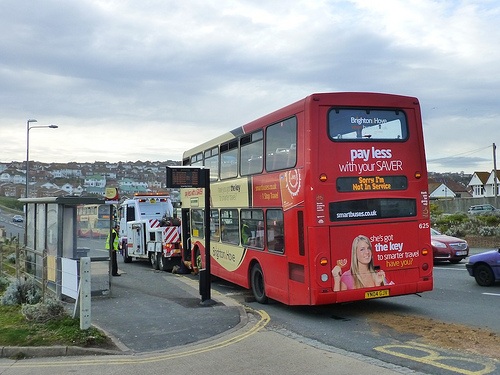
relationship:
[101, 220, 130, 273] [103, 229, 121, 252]
man wearing safety attire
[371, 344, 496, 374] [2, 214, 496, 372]
letter b on street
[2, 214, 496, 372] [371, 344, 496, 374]
street has letter b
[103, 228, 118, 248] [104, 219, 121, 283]
vest on man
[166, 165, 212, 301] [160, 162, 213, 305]
sign at bus stop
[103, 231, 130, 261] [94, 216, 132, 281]
vest on worker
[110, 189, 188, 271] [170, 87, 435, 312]
truck pulling a bus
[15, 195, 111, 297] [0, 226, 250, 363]
shelter at station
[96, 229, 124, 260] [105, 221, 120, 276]
vest on man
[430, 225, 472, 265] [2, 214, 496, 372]
car on street